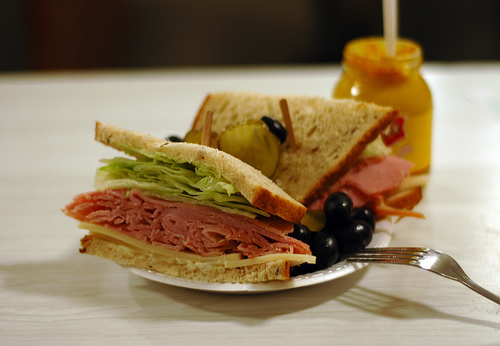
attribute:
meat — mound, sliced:
[78, 189, 294, 266]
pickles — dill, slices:
[183, 109, 296, 190]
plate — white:
[182, 275, 277, 303]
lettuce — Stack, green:
[93, 147, 237, 211]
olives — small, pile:
[290, 192, 380, 275]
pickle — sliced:
[217, 117, 279, 154]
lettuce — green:
[127, 159, 244, 204]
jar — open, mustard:
[314, 22, 446, 239]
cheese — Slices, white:
[244, 242, 305, 325]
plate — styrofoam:
[211, 250, 344, 346]